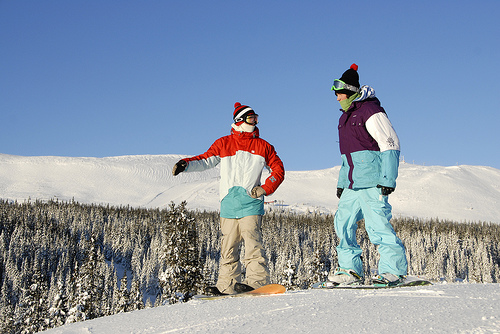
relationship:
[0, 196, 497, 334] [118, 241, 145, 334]
forest in water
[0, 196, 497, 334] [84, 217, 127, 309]
forest in water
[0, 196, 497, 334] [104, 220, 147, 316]
forest in water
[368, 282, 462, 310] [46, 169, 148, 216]
snow on ground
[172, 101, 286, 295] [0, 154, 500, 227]
friend on sunny hills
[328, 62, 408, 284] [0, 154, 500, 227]
friend on sunny hills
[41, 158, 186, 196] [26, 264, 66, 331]
snow covered trees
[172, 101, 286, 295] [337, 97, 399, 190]
friend in jacket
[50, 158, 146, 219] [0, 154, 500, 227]
snow above tree line covered hills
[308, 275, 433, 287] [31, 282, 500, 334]
snow board prepare to go down hill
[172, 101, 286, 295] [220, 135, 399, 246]
friend fully cloths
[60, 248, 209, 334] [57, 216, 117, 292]
snow hill and trees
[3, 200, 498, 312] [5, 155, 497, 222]
forest dusted with snow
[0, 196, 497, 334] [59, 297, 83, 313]
forest covered in white snow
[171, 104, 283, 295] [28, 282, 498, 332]
friend getting ready to go down hill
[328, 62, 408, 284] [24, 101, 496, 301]
friend on mountain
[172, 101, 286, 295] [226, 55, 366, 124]
friend wearing hats